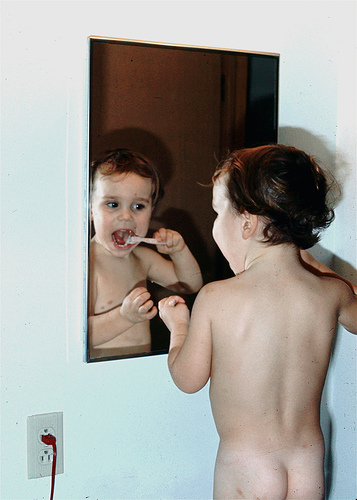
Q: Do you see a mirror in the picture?
A: Yes, there is a mirror.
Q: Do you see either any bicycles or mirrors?
A: Yes, there is a mirror.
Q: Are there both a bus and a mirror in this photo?
A: No, there is a mirror but no buses.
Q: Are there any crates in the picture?
A: No, there are no crates.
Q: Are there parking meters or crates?
A: No, there are no crates or parking meters.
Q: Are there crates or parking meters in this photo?
A: No, there are no crates or parking meters.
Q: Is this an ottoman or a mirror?
A: This is a mirror.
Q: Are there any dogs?
A: No, there are no dogs.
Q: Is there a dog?
A: No, there are no dogs.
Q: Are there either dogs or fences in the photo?
A: No, there are no dogs or fences.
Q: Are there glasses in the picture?
A: No, there are no glasses.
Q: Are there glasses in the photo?
A: No, there are no glasses.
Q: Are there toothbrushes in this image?
A: Yes, there is a toothbrush.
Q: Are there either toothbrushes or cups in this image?
A: Yes, there is a toothbrush.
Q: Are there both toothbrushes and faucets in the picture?
A: No, there is a toothbrush but no faucets.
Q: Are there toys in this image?
A: No, there are no toys.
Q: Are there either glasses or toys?
A: No, there are no toys or glasses.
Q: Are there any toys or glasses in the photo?
A: No, there are no toys or glasses.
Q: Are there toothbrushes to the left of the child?
A: Yes, there is a toothbrush to the left of the child.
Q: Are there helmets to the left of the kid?
A: No, there is a toothbrush to the left of the kid.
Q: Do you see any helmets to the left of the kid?
A: No, there is a toothbrush to the left of the kid.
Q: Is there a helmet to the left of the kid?
A: No, there is a toothbrush to the left of the kid.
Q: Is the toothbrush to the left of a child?
A: Yes, the toothbrush is to the left of a child.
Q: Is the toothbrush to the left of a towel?
A: No, the toothbrush is to the left of a child.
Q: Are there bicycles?
A: No, there are no bicycles.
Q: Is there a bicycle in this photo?
A: No, there are no bicycles.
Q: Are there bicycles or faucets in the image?
A: No, there are no bicycles or faucets.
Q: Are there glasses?
A: No, there are no glasses.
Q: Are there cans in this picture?
A: No, there are no cans.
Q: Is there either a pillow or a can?
A: No, there are no cans or pillows.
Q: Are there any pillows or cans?
A: No, there are no cans or pillows.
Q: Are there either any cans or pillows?
A: No, there are no cans or pillows.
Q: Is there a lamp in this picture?
A: No, there are no lamps.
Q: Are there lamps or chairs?
A: No, there are no lamps or chairs.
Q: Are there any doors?
A: Yes, there is a door.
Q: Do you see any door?
A: Yes, there is a door.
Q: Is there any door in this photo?
A: Yes, there is a door.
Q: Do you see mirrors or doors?
A: Yes, there is a door.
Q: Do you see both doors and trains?
A: No, there is a door but no trains.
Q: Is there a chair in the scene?
A: No, there are no chairs.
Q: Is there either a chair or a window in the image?
A: No, there are no chairs or windows.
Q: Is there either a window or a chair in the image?
A: No, there are no chairs or windows.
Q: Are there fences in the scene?
A: No, there are no fences.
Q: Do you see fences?
A: No, there are no fences.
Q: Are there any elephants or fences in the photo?
A: No, there are no fences or elephants.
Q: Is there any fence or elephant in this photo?
A: No, there are no fences or elephants.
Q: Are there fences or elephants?
A: No, there are no fences or elephants.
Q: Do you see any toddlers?
A: Yes, there is a toddler.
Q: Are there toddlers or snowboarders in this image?
A: Yes, there is a toddler.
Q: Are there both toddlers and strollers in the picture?
A: No, there is a toddler but no strollers.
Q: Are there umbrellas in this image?
A: No, there are no umbrellas.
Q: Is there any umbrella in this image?
A: No, there are no umbrellas.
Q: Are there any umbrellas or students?
A: No, there are no umbrellas or students.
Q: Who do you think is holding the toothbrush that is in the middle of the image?
A: The toddler is holding the toothbrush.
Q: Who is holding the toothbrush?
A: The toddler is holding the toothbrush.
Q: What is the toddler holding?
A: The toddler is holding the toothbrush.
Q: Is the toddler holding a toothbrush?
A: Yes, the toddler is holding a toothbrush.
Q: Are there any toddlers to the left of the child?
A: Yes, there is a toddler to the left of the child.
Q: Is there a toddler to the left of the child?
A: Yes, there is a toddler to the left of the child.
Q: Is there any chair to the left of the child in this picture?
A: No, there is a toddler to the left of the child.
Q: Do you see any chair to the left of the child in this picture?
A: No, there is a toddler to the left of the child.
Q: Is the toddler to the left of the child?
A: Yes, the toddler is to the left of the child.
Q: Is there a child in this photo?
A: Yes, there is a child.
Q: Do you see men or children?
A: Yes, there is a child.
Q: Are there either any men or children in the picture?
A: Yes, there is a child.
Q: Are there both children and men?
A: No, there is a child but no men.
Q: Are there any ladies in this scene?
A: No, there are no ladies.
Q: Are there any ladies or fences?
A: No, there are no ladies or fences.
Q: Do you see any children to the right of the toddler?
A: Yes, there is a child to the right of the toddler.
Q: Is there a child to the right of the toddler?
A: Yes, there is a child to the right of the toddler.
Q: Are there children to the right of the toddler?
A: Yes, there is a child to the right of the toddler.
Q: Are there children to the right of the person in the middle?
A: Yes, there is a child to the right of the toddler.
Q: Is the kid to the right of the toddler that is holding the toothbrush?
A: Yes, the kid is to the right of the toddler.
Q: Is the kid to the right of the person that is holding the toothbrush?
A: Yes, the kid is to the right of the toddler.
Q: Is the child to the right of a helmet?
A: No, the child is to the right of the toddler.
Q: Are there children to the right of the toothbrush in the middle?
A: Yes, there is a child to the right of the toothbrush.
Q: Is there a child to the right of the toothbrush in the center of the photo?
A: Yes, there is a child to the right of the toothbrush.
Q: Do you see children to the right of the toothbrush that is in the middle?
A: Yes, there is a child to the right of the toothbrush.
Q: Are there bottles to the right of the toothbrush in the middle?
A: No, there is a child to the right of the toothbrush.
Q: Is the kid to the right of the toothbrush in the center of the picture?
A: Yes, the kid is to the right of the toothbrush.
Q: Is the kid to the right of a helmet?
A: No, the kid is to the right of the toothbrush.